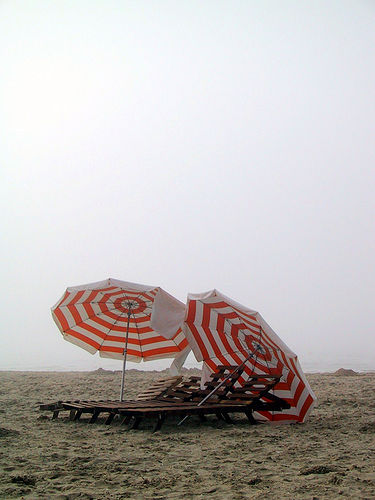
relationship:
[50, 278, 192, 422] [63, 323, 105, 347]
beach umbrella has stripes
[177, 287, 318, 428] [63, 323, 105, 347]
beach umbrella has stripes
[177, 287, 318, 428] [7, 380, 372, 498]
beach umbrella touching ground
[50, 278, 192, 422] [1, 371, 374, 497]
beach umbrella on beach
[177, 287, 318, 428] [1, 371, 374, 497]
beach umbrella on beach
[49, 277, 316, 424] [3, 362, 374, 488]
two umbrellas on beach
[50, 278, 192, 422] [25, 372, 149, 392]
beach umbrella on beach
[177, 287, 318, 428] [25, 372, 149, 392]
beach umbrella on beach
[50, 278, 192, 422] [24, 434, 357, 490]
beach umbrella on sand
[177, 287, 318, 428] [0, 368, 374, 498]
beach umbrella on sand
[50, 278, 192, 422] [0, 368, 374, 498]
beach umbrella on sand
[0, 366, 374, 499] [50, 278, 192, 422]
beach with beach umbrella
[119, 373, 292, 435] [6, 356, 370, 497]
bench on beach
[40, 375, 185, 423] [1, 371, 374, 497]
benches/umbrellas on beach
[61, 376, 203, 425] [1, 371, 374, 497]
benches on beach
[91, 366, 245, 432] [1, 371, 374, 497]
benches on beach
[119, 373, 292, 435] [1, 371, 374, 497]
bench on beach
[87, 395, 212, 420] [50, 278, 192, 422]
benches under beach umbrella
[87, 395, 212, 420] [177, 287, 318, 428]
benches under beach umbrella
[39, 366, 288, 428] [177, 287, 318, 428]
benches under beach umbrella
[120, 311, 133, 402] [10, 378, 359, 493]
pole on beach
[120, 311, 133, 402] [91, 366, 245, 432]
pole attached to benches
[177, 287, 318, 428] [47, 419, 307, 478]
beach umbrella in sand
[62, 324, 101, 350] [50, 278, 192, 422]
stripe on beach umbrella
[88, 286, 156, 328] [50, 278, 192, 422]
metal for beach umbrella